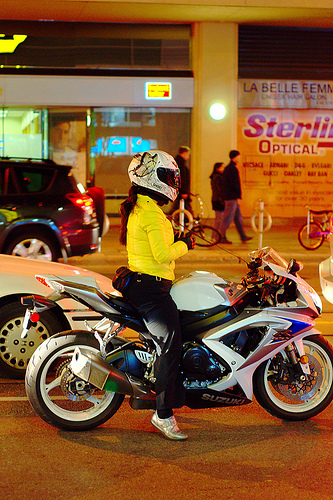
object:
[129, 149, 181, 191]
helmet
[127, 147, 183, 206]
head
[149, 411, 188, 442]
shoe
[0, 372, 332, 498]
street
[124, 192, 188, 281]
jacket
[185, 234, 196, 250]
gloves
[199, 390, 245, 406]
company name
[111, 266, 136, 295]
fanny pack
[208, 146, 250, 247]
couple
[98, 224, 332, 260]
sidewalk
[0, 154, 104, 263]
suv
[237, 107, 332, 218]
advertisement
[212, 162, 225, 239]
people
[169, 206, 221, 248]
bicycle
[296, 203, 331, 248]
bicycle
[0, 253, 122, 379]
car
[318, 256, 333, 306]
car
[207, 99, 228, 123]
light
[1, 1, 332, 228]
building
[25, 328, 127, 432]
tire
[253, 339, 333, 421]
tire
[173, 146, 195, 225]
man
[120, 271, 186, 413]
pants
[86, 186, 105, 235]
spare tire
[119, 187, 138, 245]
ponytail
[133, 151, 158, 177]
butterfly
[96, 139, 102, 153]
lights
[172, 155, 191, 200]
jacket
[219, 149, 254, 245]
man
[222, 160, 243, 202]
jacket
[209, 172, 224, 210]
jacket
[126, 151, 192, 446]
girl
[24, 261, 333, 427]
motorcycle